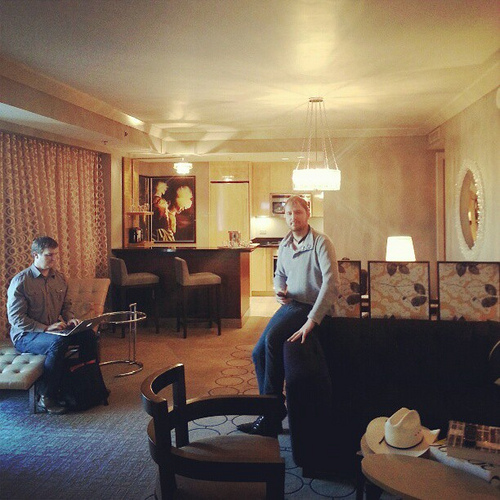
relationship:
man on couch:
[232, 182, 362, 439] [289, 311, 499, 480]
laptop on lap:
[45, 312, 112, 337] [24, 325, 95, 339]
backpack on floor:
[58, 341, 115, 411] [16, 287, 496, 500]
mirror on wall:
[452, 164, 483, 262] [440, 87, 499, 179]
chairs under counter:
[110, 254, 229, 340] [104, 240, 256, 311]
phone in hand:
[272, 283, 339, 321] [261, 279, 328, 329]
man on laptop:
[7, 235, 100, 415] [42, 310, 105, 339]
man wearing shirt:
[7, 235, 100, 415] [7, 270, 78, 329]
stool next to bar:
[121, 244, 259, 328] [134, 231, 249, 301]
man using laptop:
[7, 235, 100, 415] [47, 312, 107, 337]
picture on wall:
[135, 175, 196, 247] [127, 155, 434, 282]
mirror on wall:
[441, 154, 472, 255] [436, 162, 496, 273]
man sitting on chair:
[232, 182, 362, 439] [0, 350, 77, 430]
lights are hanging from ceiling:
[290, 93, 356, 204] [2, 3, 498, 139]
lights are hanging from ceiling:
[160, 134, 198, 190] [2, 3, 498, 139]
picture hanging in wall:
[135, 175, 196, 247] [119, 130, 431, 292]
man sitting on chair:
[7, 235, 100, 415] [1, 277, 108, 412]